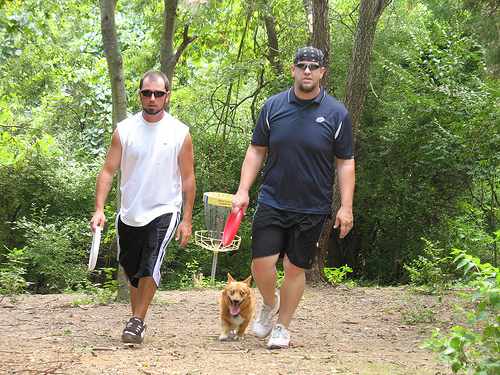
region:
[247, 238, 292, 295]
right knee of guy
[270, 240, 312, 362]
left knee of guy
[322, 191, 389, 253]
left hand of guy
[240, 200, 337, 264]
black shorts of guy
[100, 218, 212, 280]
black and white guys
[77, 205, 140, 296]
white frisbee in hand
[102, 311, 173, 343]
left shoe on guy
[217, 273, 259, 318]
head of small dog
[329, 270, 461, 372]
brown gravel by guys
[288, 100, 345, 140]
logo on polo shirt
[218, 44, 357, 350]
a man carrying a frisbee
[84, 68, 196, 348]
a man carrying a frisbee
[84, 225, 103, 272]
a white round frisbee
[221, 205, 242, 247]
a round red frisbee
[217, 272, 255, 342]
a short brown dog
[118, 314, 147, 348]
a black and white shoe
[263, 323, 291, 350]
a red and white shoe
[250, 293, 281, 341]
a red and white shoe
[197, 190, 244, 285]
a yellow frisbee net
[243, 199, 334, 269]
a pair of black shorts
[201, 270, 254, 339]
brown and white dog panting in the woods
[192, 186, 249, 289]
yellow Frisbee golf stand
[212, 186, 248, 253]
red Frisbee in man's hand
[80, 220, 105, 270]
white Frisbee in man's hand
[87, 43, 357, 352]
two men walking in the woods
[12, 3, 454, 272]
large green trees in the woods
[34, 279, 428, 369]
dirt path in the woods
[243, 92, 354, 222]
dark blue shirt on man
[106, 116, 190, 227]
white t-shirt on man in woods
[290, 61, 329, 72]
black sunglasses on man in woods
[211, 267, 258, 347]
corgi walking in the woods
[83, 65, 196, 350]
man carrying a Frisbee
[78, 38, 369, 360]
two men playing Frisbee golf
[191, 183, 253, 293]
Frisbee golf target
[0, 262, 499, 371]
trail leading through the forest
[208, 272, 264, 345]
the dog's mouth is open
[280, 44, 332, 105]
he is wearing sunglasses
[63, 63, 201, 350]
man wearing a white shirt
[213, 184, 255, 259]
red plastic flying disc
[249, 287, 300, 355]
he is wearing white sneakers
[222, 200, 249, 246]
a red Frisbee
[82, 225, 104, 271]
a white Frisbee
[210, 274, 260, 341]
a small brown dog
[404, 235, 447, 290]
green tree leaves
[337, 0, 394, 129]
part of a long tree branch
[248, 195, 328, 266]
a man's black shorts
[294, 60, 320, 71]
dark black sunglasses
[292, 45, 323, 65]
a black and white bandanna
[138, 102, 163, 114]
a man's black beard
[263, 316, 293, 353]
a man's white tennis shoe